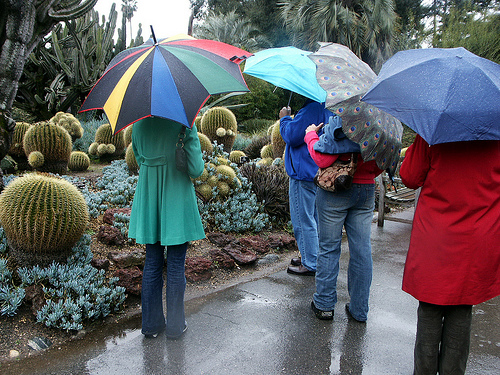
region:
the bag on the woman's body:
[314, 150, 356, 193]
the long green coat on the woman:
[127, 118, 205, 246]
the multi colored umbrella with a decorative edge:
[79, 24, 254, 139]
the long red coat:
[397, 134, 498, 306]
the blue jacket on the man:
[277, 100, 336, 181]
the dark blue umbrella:
[361, 45, 498, 144]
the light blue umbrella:
[242, 45, 325, 104]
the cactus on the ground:
[2, 108, 295, 338]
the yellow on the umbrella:
[102, 34, 197, 130]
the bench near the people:
[375, 163, 420, 226]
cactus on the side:
[10, 173, 92, 255]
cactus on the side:
[218, 183, 233, 198]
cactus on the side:
[221, 166, 231, 185]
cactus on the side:
[231, 145, 259, 170]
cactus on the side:
[231, 150, 247, 165]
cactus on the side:
[212, 130, 222, 145]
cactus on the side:
[72, 151, 96, 186]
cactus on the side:
[24, 124, 65, 161]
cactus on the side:
[39, 106, 82, 142]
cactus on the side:
[83, 143, 110, 158]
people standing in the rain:
[88, 21, 499, 359]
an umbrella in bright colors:
[78, 21, 251, 152]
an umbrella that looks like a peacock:
[321, 25, 409, 180]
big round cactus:
[0, 170, 103, 282]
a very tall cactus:
[46, 15, 123, 111]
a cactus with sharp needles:
[10, 153, 100, 266]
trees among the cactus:
[214, 4, 440, 59]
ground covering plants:
[2, 263, 147, 338]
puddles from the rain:
[43, 318, 184, 362]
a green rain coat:
[131, 135, 231, 282]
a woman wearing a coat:
[66, 116, 263, 280]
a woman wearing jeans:
[119, 188, 260, 320]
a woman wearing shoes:
[125, 310, 221, 350]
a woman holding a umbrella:
[345, 51, 480, 211]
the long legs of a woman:
[126, 201, 271, 331]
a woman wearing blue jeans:
[277, 168, 397, 301]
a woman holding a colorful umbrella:
[65, 15, 336, 138]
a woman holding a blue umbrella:
[231, 22, 381, 83]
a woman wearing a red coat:
[392, 120, 497, 300]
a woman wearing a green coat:
[104, 103, 264, 252]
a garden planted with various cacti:
[0, 2, 285, 340]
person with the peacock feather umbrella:
[305, 40, 399, 322]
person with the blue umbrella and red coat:
[363, 48, 495, 374]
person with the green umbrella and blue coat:
[245, 48, 320, 275]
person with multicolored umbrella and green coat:
[80, 37, 254, 339]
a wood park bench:
[379, 168, 421, 230]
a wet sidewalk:
[5, 210, 493, 374]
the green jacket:
[127, 123, 205, 247]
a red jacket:
[400, 135, 498, 305]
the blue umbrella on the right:
[364, 42, 498, 142]